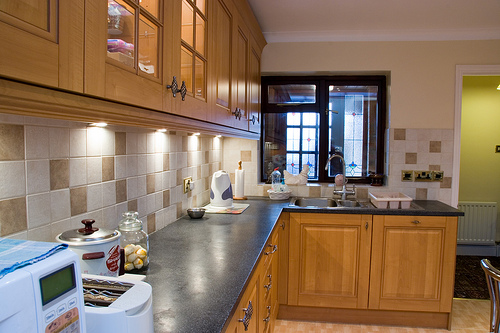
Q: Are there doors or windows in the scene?
A: Yes, there are windows.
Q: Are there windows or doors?
A: Yes, there are windows.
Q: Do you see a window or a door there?
A: Yes, there are windows.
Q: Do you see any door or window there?
A: Yes, there are windows.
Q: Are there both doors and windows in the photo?
A: Yes, there are both windows and a door.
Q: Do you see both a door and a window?
A: Yes, there are both a window and a door.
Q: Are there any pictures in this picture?
A: No, there are no pictures.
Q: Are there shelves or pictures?
A: No, there are no pictures or shelves.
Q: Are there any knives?
A: No, there are no knives.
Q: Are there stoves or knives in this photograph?
A: No, there are no knives or stoves.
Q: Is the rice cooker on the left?
A: Yes, the rice cooker is on the left of the image.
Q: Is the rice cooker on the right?
A: No, the rice cooker is on the left of the image.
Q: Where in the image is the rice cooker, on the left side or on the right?
A: The rice cooker is on the left of the image.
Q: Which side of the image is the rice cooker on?
A: The rice cooker is on the left of the image.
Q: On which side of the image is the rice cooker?
A: The rice cooker is on the left of the image.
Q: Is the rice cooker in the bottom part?
A: Yes, the rice cooker is in the bottom of the image.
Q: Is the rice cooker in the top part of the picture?
A: No, the rice cooker is in the bottom of the image.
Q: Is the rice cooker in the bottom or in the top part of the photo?
A: The rice cooker is in the bottom of the image.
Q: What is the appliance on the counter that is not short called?
A: The appliance is a rice cooker.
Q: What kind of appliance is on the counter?
A: The appliance is a rice cooker.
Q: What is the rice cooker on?
A: The rice cooker is on the counter.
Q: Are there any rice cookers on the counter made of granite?
A: Yes, there is a rice cooker on the counter.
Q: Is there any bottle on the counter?
A: No, there is a rice cooker on the counter.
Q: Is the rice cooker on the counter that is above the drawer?
A: Yes, the rice cooker is on the counter.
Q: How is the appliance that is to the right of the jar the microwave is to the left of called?
A: The appliance is a rice cooker.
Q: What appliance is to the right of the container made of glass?
A: The appliance is a rice cooker.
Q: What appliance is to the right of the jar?
A: The appliance is a rice cooker.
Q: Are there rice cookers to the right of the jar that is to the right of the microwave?
A: Yes, there is a rice cooker to the right of the jar.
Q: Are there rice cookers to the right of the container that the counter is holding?
A: Yes, there is a rice cooker to the right of the jar.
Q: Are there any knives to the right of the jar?
A: No, there is a rice cooker to the right of the jar.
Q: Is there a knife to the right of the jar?
A: No, there is a rice cooker to the right of the jar.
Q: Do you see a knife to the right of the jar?
A: No, there is a rice cooker to the right of the jar.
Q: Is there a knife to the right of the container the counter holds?
A: No, there is a rice cooker to the right of the jar.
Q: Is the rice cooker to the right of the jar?
A: Yes, the rice cooker is to the right of the jar.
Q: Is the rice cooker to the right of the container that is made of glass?
A: Yes, the rice cooker is to the right of the jar.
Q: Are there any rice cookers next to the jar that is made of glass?
A: Yes, there is a rice cooker next to the jar.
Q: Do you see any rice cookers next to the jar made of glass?
A: Yes, there is a rice cooker next to the jar.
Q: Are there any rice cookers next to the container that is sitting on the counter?
A: Yes, there is a rice cooker next to the jar.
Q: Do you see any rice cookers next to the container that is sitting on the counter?
A: Yes, there is a rice cooker next to the jar.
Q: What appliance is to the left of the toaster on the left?
A: The appliance is a rice cooker.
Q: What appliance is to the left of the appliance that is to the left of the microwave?
A: The appliance is a rice cooker.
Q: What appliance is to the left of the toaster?
A: The appliance is a rice cooker.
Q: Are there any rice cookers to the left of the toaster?
A: Yes, there is a rice cooker to the left of the toaster.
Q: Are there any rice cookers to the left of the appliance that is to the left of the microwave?
A: Yes, there is a rice cooker to the left of the toaster.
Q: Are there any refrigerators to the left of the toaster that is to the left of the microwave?
A: No, there is a rice cooker to the left of the toaster.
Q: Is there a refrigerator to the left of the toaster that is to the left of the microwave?
A: No, there is a rice cooker to the left of the toaster.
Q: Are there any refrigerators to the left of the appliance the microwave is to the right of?
A: No, there is a rice cooker to the left of the toaster.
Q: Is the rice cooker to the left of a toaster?
A: Yes, the rice cooker is to the left of a toaster.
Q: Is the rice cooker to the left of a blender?
A: No, the rice cooker is to the left of a toaster.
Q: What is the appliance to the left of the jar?
A: The appliance is a rice cooker.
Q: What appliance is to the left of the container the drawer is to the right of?
A: The appliance is a rice cooker.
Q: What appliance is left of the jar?
A: The appliance is a rice cooker.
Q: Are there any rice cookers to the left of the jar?
A: Yes, there is a rice cooker to the left of the jar.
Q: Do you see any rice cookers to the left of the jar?
A: Yes, there is a rice cooker to the left of the jar.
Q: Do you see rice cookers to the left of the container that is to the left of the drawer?
A: Yes, there is a rice cooker to the left of the jar.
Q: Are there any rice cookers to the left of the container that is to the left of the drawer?
A: Yes, there is a rice cooker to the left of the jar.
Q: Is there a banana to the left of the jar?
A: No, there is a rice cooker to the left of the jar.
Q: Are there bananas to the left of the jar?
A: No, there is a rice cooker to the left of the jar.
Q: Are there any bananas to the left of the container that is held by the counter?
A: No, there is a rice cooker to the left of the jar.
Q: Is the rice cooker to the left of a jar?
A: Yes, the rice cooker is to the left of a jar.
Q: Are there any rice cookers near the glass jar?
A: Yes, there is a rice cooker near the jar.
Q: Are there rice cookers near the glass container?
A: Yes, there is a rice cooker near the jar.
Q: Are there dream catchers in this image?
A: No, there are no dream catchers.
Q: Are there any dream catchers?
A: No, there are no dream catchers.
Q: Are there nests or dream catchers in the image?
A: No, there are no dream catchers or nests.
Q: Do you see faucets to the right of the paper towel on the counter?
A: Yes, there is a faucet to the right of the paper towel.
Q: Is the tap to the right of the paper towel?
A: Yes, the tap is to the right of the paper towel.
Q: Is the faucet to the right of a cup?
A: No, the faucet is to the right of the paper towel.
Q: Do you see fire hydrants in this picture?
A: No, there are no fire hydrants.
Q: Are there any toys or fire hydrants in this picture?
A: No, there are no fire hydrants or toys.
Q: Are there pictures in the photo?
A: No, there are no pictures.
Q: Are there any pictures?
A: No, there are no pictures.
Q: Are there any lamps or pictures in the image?
A: No, there are no pictures or lamps.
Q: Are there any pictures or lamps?
A: No, there are no pictures or lamps.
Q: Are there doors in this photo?
A: Yes, there is a door.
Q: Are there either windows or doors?
A: Yes, there is a door.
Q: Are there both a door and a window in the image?
A: Yes, there are both a door and a window.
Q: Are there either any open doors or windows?
A: Yes, there is an open door.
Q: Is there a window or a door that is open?
A: Yes, the door is open.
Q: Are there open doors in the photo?
A: Yes, there is an open door.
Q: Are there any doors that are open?
A: Yes, there is a door that is open.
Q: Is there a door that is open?
A: Yes, there is a door that is open.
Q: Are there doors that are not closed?
A: Yes, there is a open door.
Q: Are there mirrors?
A: No, there are no mirrors.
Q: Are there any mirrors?
A: No, there are no mirrors.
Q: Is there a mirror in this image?
A: No, there are no mirrors.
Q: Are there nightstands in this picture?
A: No, there are no nightstands.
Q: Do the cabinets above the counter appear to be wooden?
A: Yes, the cabinets are wooden.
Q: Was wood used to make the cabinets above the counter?
A: Yes, the cabinets are made of wood.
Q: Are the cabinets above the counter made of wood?
A: Yes, the cabinets are made of wood.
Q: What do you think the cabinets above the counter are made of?
A: The cabinets are made of wood.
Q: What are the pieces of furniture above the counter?
A: The pieces of furniture are cabinets.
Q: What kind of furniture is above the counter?
A: The pieces of furniture are cabinets.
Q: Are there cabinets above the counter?
A: Yes, there are cabinets above the counter.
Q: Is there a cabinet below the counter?
A: No, the cabinets are above the counter.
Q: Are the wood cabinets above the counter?
A: Yes, the cabinets are above the counter.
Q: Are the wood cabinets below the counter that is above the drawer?
A: No, the cabinets are above the counter.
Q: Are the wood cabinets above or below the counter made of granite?
A: The cabinets are above the counter.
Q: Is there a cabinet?
A: Yes, there is a cabinet.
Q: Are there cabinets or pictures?
A: Yes, there is a cabinet.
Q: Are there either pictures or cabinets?
A: Yes, there is a cabinet.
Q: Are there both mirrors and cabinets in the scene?
A: No, there is a cabinet but no mirrors.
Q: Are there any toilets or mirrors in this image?
A: No, there are no mirrors or toilets.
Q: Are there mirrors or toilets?
A: No, there are no mirrors or toilets.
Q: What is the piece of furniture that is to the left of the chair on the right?
A: The piece of furniture is a cabinet.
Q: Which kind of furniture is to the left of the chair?
A: The piece of furniture is a cabinet.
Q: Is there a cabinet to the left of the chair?
A: Yes, there is a cabinet to the left of the chair.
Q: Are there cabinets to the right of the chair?
A: No, the cabinet is to the left of the chair.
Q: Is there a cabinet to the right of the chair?
A: No, the cabinet is to the left of the chair.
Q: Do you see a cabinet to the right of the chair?
A: No, the cabinet is to the left of the chair.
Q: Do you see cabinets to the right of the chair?
A: No, the cabinet is to the left of the chair.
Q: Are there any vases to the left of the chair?
A: No, there is a cabinet to the left of the chair.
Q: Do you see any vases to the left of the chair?
A: No, there is a cabinet to the left of the chair.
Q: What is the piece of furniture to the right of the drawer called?
A: The piece of furniture is a cabinet.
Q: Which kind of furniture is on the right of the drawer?
A: The piece of furniture is a cabinet.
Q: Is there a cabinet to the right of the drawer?
A: Yes, there is a cabinet to the right of the drawer.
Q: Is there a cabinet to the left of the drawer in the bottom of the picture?
A: No, the cabinet is to the right of the drawer.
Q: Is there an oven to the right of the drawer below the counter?
A: No, there is a cabinet to the right of the drawer.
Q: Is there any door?
A: Yes, there are doors.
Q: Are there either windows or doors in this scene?
A: Yes, there are doors.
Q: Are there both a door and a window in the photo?
A: Yes, there are both a door and a window.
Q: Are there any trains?
A: No, there are no trains.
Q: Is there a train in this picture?
A: No, there are no trains.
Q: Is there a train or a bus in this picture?
A: No, there are no trains or buses.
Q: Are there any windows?
A: Yes, there is a window.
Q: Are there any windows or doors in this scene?
A: Yes, there is a window.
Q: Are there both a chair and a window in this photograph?
A: Yes, there are both a window and a chair.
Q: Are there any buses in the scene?
A: No, there are no buses.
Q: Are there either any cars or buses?
A: No, there are no buses or cars.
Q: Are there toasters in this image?
A: Yes, there is a toaster.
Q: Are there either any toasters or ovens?
A: Yes, there is a toaster.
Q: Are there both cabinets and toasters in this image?
A: Yes, there are both a toaster and a cabinet.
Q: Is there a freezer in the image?
A: No, there are no refrigerators.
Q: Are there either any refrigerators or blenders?
A: No, there are no refrigerators or blenders.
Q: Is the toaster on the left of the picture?
A: Yes, the toaster is on the left of the image.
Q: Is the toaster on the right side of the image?
A: No, the toaster is on the left of the image.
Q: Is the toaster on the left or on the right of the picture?
A: The toaster is on the left of the image.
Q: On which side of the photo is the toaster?
A: The toaster is on the left of the image.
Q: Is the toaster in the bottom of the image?
A: Yes, the toaster is in the bottom of the image.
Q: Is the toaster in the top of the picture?
A: No, the toaster is in the bottom of the image.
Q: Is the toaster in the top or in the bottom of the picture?
A: The toaster is in the bottom of the image.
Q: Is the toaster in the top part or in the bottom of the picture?
A: The toaster is in the bottom of the image.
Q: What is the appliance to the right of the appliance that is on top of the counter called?
A: The appliance is a toaster.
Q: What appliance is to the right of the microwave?
A: The appliance is a toaster.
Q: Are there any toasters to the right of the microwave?
A: Yes, there is a toaster to the right of the microwave.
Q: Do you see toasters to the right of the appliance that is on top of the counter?
A: Yes, there is a toaster to the right of the microwave.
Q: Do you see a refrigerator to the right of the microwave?
A: No, there is a toaster to the right of the microwave.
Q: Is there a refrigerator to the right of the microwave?
A: No, there is a toaster to the right of the microwave.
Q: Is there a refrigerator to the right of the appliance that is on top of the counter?
A: No, there is a toaster to the right of the microwave.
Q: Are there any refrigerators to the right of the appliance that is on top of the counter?
A: No, there is a toaster to the right of the microwave.